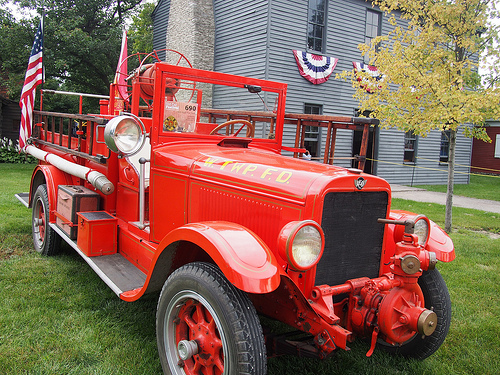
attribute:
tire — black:
[371, 262, 452, 360]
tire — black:
[154, 252, 269, 373]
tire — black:
[27, 179, 62, 261]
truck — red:
[12, 48, 459, 373]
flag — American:
[3, 17, 70, 145]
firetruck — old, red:
[17, 60, 449, 358]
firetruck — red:
[16, 48, 459, 374]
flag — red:
[107, 33, 136, 102]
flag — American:
[15, 17, 57, 187]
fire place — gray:
[150, 0, 212, 132]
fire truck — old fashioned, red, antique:
[23, 58, 449, 373]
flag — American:
[15, 24, 43, 156]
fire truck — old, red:
[19, 26, 459, 362]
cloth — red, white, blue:
[289, 49, 344, 86]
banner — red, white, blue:
[291, 51, 347, 83]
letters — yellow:
[211, 155, 299, 182]